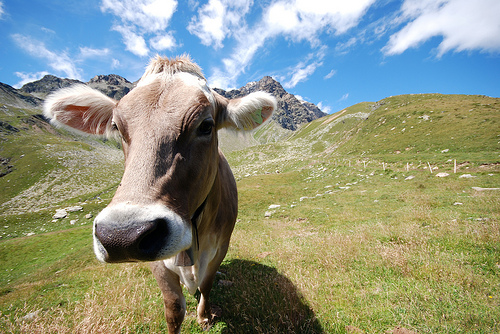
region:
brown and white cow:
[27, 29, 274, 290]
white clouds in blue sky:
[29, 10, 86, 40]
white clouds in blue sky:
[23, 10, 141, 74]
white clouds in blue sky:
[456, 21, 487, 82]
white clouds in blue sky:
[343, 19, 404, 76]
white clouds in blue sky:
[271, 19, 326, 56]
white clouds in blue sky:
[159, 23, 254, 40]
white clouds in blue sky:
[83, 9, 167, 43]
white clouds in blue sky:
[313, 1, 428, 75]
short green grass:
[329, 154, 407, 256]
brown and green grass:
[311, 200, 420, 297]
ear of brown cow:
[10, 82, 106, 141]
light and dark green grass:
[12, 4, 79, 36]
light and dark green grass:
[2, 36, 48, 68]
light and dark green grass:
[71, 19, 122, 67]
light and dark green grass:
[422, 19, 459, 69]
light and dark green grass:
[337, 8, 426, 85]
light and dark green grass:
[264, 8, 328, 49]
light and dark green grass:
[202, 12, 259, 65]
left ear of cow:
[226, 79, 277, 141]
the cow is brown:
[48, 46, 308, 293]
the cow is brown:
[45, 49, 224, 210]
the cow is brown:
[204, 196, 255, 290]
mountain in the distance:
[226, 55, 338, 155]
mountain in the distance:
[207, 59, 312, 129]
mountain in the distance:
[14, 67, 124, 112]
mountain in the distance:
[14, 54, 141, 145]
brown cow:
[15, 53, 251, 313]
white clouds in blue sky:
[7, 11, 51, 47]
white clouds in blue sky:
[3, 28, 81, 72]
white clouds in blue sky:
[175, 9, 283, 37]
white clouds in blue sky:
[244, 3, 349, 43]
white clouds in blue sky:
[225, 56, 314, 73]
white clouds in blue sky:
[301, 36, 380, 74]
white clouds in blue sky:
[378, 13, 454, 59]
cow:
[61, 60, 258, 291]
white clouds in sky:
[236, 13, 348, 58]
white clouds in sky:
[351, 11, 458, 74]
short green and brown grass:
[334, 120, 409, 158]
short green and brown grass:
[427, 117, 459, 194]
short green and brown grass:
[333, 133, 425, 191]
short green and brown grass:
[273, 180, 408, 246]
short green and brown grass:
[370, 257, 449, 295]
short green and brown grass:
[12, 216, 72, 291]